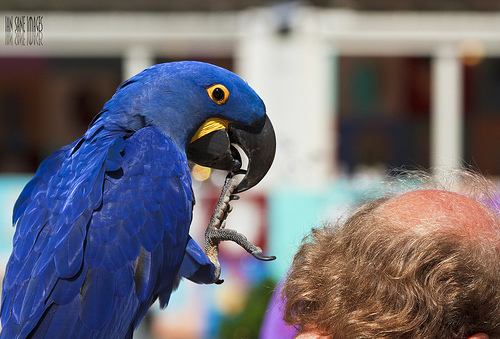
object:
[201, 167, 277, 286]
claw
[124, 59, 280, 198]
head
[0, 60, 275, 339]
bird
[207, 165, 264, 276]
feet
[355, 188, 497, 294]
bald spot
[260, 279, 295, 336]
purple background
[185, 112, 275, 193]
parrot's beak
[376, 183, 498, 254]
spot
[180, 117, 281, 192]
mouth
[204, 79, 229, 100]
eye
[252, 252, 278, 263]
talon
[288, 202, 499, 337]
hair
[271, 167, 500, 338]
head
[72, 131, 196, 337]
right wing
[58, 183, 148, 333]
feather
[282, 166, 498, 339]
man